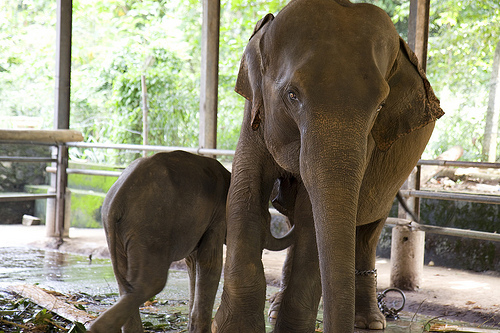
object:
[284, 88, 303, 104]
eye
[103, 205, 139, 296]
tail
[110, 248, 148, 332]
legs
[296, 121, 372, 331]
trunk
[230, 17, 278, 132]
ear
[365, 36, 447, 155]
ear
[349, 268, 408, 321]
chain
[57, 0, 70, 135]
beam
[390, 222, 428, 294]
cement block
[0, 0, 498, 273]
trees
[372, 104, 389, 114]
eyes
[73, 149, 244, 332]
elephant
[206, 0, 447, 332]
elephant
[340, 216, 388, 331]
leg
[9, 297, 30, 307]
leaves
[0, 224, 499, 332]
ground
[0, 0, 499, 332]
background